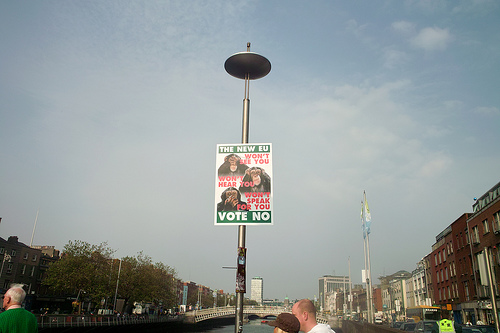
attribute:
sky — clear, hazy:
[1, 0, 500, 301]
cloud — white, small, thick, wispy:
[406, 27, 451, 53]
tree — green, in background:
[39, 240, 115, 318]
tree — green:
[112, 252, 158, 317]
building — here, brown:
[465, 181, 500, 332]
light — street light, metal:
[237, 246, 246, 279]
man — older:
[0, 285, 41, 333]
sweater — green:
[0, 307, 39, 332]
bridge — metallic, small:
[184, 306, 235, 324]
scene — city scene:
[0, 0, 498, 332]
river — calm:
[198, 322, 235, 333]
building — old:
[425, 204, 471, 317]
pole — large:
[234, 40, 251, 333]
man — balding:
[292, 298, 337, 332]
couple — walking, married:
[273, 298, 335, 332]